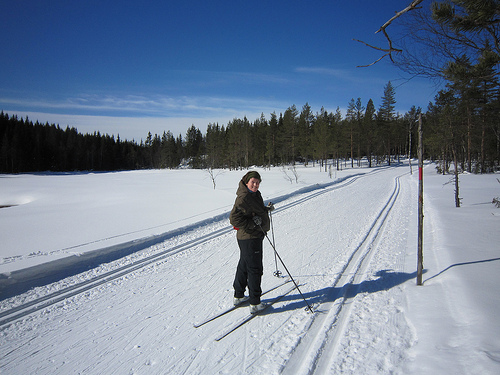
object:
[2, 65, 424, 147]
clouds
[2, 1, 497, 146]
sky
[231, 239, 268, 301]
snow pants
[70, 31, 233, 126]
clouds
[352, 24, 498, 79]
branches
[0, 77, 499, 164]
tree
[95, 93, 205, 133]
clouds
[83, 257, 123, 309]
snow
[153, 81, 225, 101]
clouds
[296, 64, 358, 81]
cloud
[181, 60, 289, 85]
cloud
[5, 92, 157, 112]
cloud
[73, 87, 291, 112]
cloud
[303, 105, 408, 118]
cloud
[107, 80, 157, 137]
clouds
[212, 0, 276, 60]
clouds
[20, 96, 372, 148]
cloud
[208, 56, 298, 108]
clouds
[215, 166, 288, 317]
woman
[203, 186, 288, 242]
jacket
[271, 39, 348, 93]
clouds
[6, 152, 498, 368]
snow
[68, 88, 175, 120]
clouds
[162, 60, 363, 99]
clouds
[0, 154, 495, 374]
ground